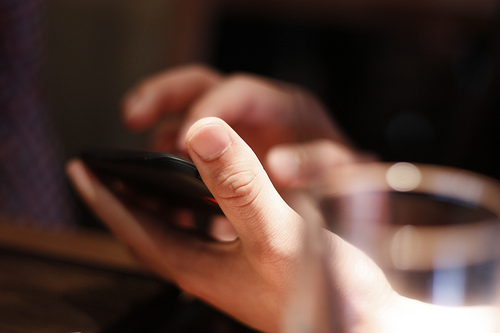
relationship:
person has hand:
[58, 62, 498, 332] [121, 64, 386, 242]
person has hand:
[58, 62, 498, 332] [64, 115, 390, 332]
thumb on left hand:
[181, 113, 298, 256] [144, 222, 347, 332]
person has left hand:
[307, 209, 481, 331] [144, 222, 347, 332]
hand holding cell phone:
[64, 115, 390, 332] [77, 144, 236, 214]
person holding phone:
[58, 62, 498, 332] [80, 145, 225, 215]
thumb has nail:
[175, 108, 300, 245] [187, 125, 234, 157]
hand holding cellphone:
[64, 115, 390, 332] [78, 135, 226, 205]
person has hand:
[58, 62, 498, 332] [119, 62, 381, 190]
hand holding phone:
[64, 115, 390, 332] [81, 122, 316, 259]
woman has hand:
[66, 65, 496, 332] [64, 115, 390, 332]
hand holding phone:
[107, 85, 440, 318] [65, 118, 240, 216]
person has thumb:
[58, 62, 498, 332] [183, 113, 288, 246]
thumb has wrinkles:
[183, 113, 288, 246] [212, 163, 259, 212]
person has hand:
[58, 62, 498, 332] [48, 106, 493, 326]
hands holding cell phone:
[61, 60, 435, 331] [63, 128, 261, 252]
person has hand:
[58, 62, 498, 332] [69, 122, 406, 307]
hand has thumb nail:
[69, 122, 406, 307] [185, 127, 238, 159]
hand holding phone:
[64, 115, 390, 332] [83, 138, 231, 221]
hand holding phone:
[118, 55, 418, 297] [83, 138, 231, 221]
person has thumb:
[58, 62, 498, 332] [181, 113, 298, 256]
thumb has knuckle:
[181, 113, 298, 256] [219, 227, 320, 305]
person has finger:
[184, 111, 300, 265] [181, 113, 292, 245]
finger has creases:
[181, 113, 292, 245] [212, 166, 269, 218]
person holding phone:
[58, 62, 498, 332] [67, 145, 229, 216]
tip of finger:
[61, 158, 93, 184] [91, 185, 156, 240]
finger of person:
[168, 112, 352, 312] [83, 61, 483, 317]